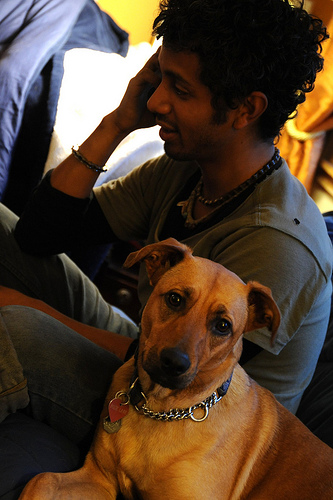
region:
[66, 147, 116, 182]
bracelet on man's arm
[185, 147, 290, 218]
necklace on man's neck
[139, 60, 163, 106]
blue phone in man's hand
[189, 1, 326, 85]
man's curly black hair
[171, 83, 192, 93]
the man's left eye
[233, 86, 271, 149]
the man's left ear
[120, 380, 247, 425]
collar around dog's neck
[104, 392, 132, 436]
charm on dog's collar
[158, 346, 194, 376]
black nose on the dog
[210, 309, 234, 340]
the dog's left eye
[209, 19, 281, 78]
black curls on a head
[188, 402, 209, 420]
a metal loop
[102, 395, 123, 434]
metal shaped dog tags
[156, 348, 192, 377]
a black nose with nostrils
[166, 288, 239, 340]
sad brown eyes looking at the camera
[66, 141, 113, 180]
a beaded bracelet on an arm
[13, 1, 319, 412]
a guy talking on the cell phone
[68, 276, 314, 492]
a brown dog sitting next to a man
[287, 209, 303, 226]
a hole in a blue t-shirt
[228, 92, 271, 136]
an ear on a head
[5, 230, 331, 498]
Large brown dog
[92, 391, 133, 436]
Small red tag on dog collar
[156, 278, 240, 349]
Two small black eyes on dog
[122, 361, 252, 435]
Chain link dog collar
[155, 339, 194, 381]
Black nose on dog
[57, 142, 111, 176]
Black bracelt on mans wrist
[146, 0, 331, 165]
Dark brown curly hair on man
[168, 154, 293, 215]
Black beaded necklace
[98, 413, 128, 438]
Silver tag on dog collar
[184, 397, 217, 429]
Silver attachment ring on dog collar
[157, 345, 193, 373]
dog's black shiny nose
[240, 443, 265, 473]
muscle in dog's neck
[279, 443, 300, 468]
brown fur on dog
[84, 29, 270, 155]
man talking on phone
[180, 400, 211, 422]
small gold ring of dog's neck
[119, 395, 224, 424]
gold chain around neck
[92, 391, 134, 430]
red dog tags on neck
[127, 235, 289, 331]
dog's floppy brown ears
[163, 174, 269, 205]
black necklace around neck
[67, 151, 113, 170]
black wrist band around wrist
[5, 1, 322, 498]
man and dog sitting together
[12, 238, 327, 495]
dog is golden brown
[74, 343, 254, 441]
dog wearing chain collar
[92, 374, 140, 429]
heart on chain collar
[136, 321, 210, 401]
black nose on dog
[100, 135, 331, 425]
man wearing blue shirt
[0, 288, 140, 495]
man wearing blue jeans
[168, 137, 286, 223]
man wearing black necklace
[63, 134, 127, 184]
man wearing a bracelet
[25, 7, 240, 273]
man holding arm up